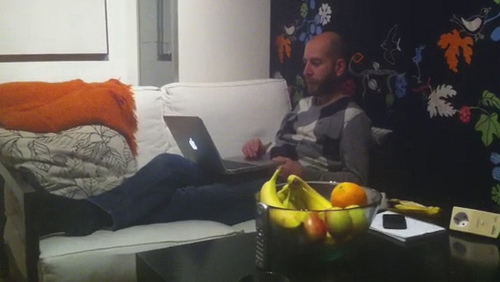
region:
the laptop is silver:
[159, 95, 321, 212]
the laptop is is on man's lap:
[146, 18, 385, 255]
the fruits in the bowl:
[270, 166, 386, 250]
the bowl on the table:
[230, 150, 389, 274]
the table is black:
[162, 240, 218, 280]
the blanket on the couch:
[10, 76, 165, 148]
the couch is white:
[116, 80, 308, 157]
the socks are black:
[26, 177, 139, 259]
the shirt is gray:
[260, 86, 377, 200]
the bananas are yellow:
[265, 171, 342, 221]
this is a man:
[222, 35, 375, 168]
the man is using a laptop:
[160, 102, 267, 179]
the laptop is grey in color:
[165, 112, 217, 149]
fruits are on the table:
[264, 177, 360, 242]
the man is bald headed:
[317, 28, 335, 46]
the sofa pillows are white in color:
[148, 82, 273, 117]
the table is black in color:
[203, 245, 223, 271]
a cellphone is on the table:
[378, 210, 410, 226]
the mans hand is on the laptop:
[236, 137, 267, 154]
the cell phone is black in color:
[387, 215, 405, 225]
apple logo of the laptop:
[171, 135, 201, 157]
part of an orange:
[333, 182, 358, 206]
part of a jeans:
[139, 172, 182, 199]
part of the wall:
[397, 13, 489, 138]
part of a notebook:
[418, 219, 433, 237]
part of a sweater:
[298, 111, 348, 155]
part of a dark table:
[148, 237, 205, 279]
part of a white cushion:
[195, 85, 272, 148]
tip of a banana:
[263, 166, 278, 196]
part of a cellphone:
[246, 182, 271, 257]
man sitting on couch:
[0, 23, 410, 230]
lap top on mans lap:
[119, 15, 381, 195]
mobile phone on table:
[239, 181, 310, 280]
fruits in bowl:
[244, 160, 442, 274]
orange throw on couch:
[8, 66, 140, 177]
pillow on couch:
[13, 92, 143, 229]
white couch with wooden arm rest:
[1, 67, 375, 279]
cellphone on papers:
[367, 205, 437, 247]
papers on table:
[345, 186, 482, 253]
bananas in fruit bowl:
[246, 165, 361, 250]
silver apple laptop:
[162, 112, 283, 177]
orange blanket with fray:
[0, 71, 137, 146]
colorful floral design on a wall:
[271, 2, 498, 182]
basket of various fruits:
[262, 164, 375, 245]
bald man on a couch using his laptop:
[73, 19, 369, 228]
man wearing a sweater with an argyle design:
[250, 28, 366, 188]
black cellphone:
[380, 204, 409, 233]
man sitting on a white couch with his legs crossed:
[67, 24, 367, 241]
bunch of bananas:
[257, 169, 331, 236]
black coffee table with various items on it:
[131, 191, 498, 279]